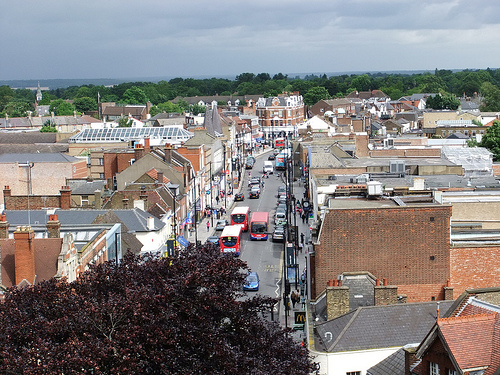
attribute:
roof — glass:
[71, 130, 189, 144]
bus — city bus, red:
[250, 209, 277, 245]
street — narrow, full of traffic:
[265, 249, 278, 286]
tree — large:
[68, 287, 219, 363]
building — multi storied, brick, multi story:
[315, 200, 463, 338]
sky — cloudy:
[255, 14, 472, 63]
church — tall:
[32, 81, 63, 123]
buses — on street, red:
[218, 205, 272, 263]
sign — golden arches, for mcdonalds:
[290, 308, 310, 337]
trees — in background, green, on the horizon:
[134, 79, 272, 95]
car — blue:
[238, 264, 269, 295]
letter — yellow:
[171, 236, 195, 265]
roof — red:
[439, 316, 498, 362]